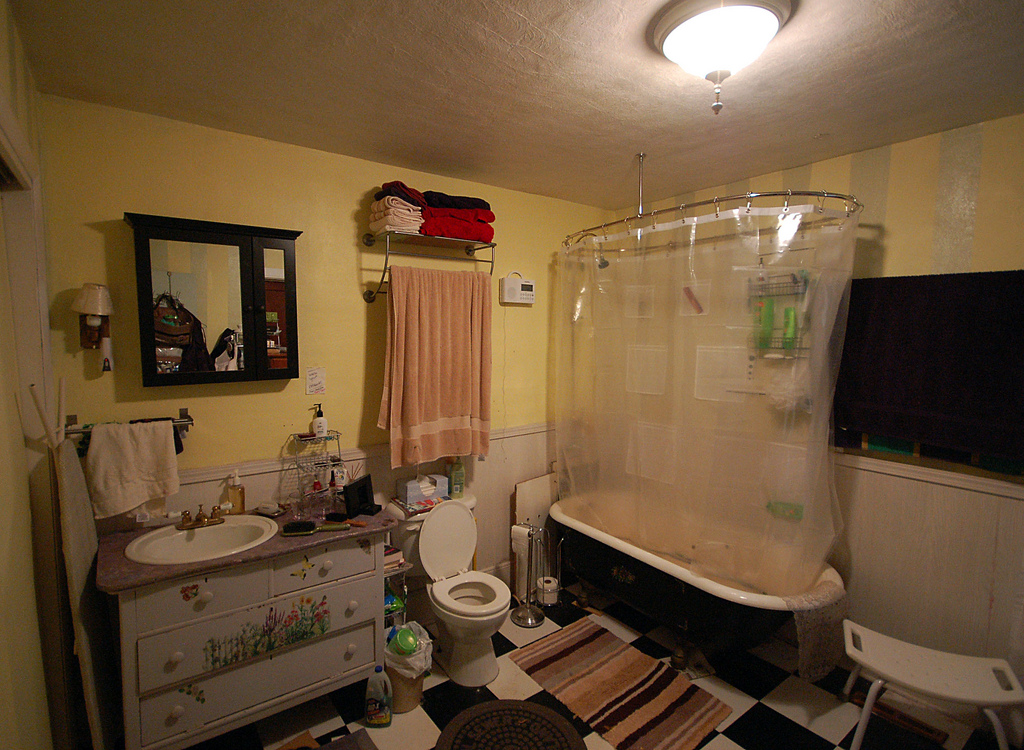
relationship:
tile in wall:
[861, 125, 1014, 277] [604, 94, 1021, 658]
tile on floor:
[759, 673, 861, 745] [196, 558, 1019, 746]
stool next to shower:
[840, 617, 1023, 750] [536, 181, 863, 703]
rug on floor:
[513, 609, 730, 745] [196, 558, 1019, 746]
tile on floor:
[487, 645, 554, 716] [208, 587, 978, 746]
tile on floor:
[412, 675, 505, 730] [208, 587, 978, 746]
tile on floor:
[759, 673, 861, 745] [208, 587, 978, 746]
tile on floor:
[687, 670, 758, 737] [208, 587, 978, 746]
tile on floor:
[716, 703, 830, 739] [286, 608, 989, 741]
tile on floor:
[417, 678, 500, 732] [286, 608, 989, 741]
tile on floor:
[748, 684, 856, 738] [208, 587, 978, 746]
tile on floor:
[498, 601, 559, 644] [208, 587, 978, 746]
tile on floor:
[759, 673, 861, 745] [25, 577, 1022, 745]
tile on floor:
[759, 673, 861, 745] [415, 589, 973, 725]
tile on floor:
[759, 673, 861, 745] [123, 534, 949, 734]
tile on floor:
[750, 627, 814, 681] [196, 558, 1019, 746]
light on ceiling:
[642, 0, 798, 127] [32, 5, 1019, 215]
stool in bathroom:
[834, 611, 1015, 744] [1, 0, 1020, 748]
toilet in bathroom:
[394, 490, 519, 696] [1, 0, 1020, 748]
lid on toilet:
[423, 503, 471, 573] [417, 488, 515, 691]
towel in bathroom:
[365, 248, 474, 454] [130, 136, 900, 665]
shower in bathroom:
[544, 192, 867, 667] [1, 0, 1020, 748]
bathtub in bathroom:
[551, 487, 843, 653] [28, 135, 1012, 740]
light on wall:
[74, 279, 119, 366] [39, 95, 610, 634]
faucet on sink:
[173, 500, 222, 529] [129, 496, 278, 564]